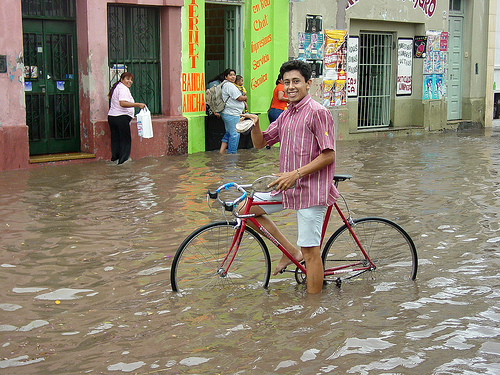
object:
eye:
[294, 80, 299, 84]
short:
[250, 187, 331, 250]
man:
[228, 51, 334, 296]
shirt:
[263, 96, 346, 208]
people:
[212, 68, 248, 156]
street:
[0, 134, 500, 375]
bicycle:
[168, 168, 420, 295]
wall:
[239, 1, 271, 115]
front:
[359, 33, 395, 130]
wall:
[396, 0, 422, 133]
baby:
[235, 75, 249, 110]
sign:
[181, 0, 205, 114]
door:
[19, 0, 81, 158]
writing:
[179, 0, 204, 67]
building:
[0, 5, 500, 166]